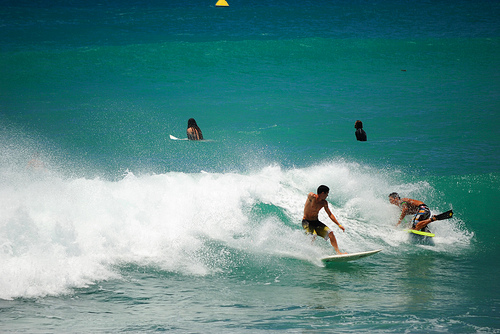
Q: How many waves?
A: One.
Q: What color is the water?
A: Blue.